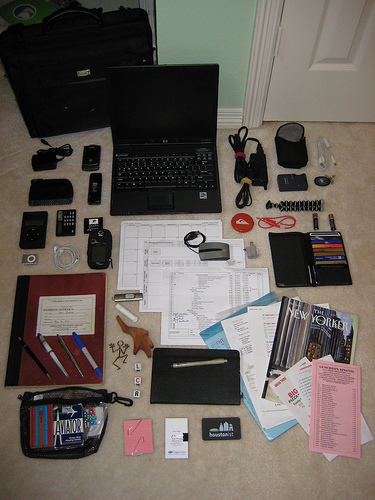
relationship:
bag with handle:
[0, 5, 161, 141] [35, 4, 107, 29]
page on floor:
[306, 356, 368, 462] [6, 119, 374, 499]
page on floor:
[290, 366, 312, 399] [6, 119, 374, 499]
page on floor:
[268, 378, 302, 426] [6, 119, 374, 499]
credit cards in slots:
[304, 225, 352, 272] [304, 225, 358, 288]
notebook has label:
[3, 265, 112, 390] [31, 290, 105, 340]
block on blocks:
[112, 214, 229, 242] [112, 220, 233, 235]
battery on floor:
[78, 172, 112, 213] [6, 119, 374, 499]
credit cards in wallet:
[304, 225, 352, 272] [264, 225, 360, 297]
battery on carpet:
[78, 139, 106, 175] [6, 119, 374, 499]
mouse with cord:
[181, 225, 237, 266] [180, 228, 209, 250]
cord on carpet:
[224, 122, 260, 214] [6, 119, 374, 499]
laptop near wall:
[97, 53, 233, 220] [158, 4, 257, 65]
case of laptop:
[143, 341, 253, 410] [97, 53, 233, 220]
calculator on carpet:
[52, 200, 82, 243] [6, 119, 374, 499]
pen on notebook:
[71, 329, 94, 357] [3, 265, 112, 390]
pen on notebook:
[59, 331, 73, 357] [3, 265, 112, 390]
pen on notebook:
[35, 330, 53, 353] [3, 265, 112, 390]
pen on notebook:
[10, 330, 33, 359] [3, 265, 112, 390]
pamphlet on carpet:
[271, 291, 372, 364] [6, 119, 374, 499]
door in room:
[260, 4, 374, 129] [9, 1, 374, 497]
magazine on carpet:
[271, 291, 372, 364] [6, 119, 374, 499]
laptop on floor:
[97, 53, 233, 220] [6, 119, 374, 499]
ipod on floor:
[83, 224, 115, 274] [6, 119, 374, 499]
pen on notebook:
[71, 329, 104, 381] [3, 265, 112, 390]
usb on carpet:
[323, 209, 345, 234] [6, 119, 374, 499]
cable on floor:
[35, 132, 80, 162] [6, 119, 374, 499]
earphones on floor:
[306, 132, 347, 194] [6, 119, 374, 499]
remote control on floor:
[83, 166, 106, 209] [6, 119, 374, 499]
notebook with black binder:
[3, 265, 112, 390] [3, 267, 29, 396]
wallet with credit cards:
[264, 225, 360, 297] [304, 225, 352, 272]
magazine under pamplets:
[271, 291, 372, 364] [206, 302, 297, 441]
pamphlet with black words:
[306, 356, 368, 462] [313, 363, 358, 451]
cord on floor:
[224, 122, 260, 214] [6, 119, 374, 499]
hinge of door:
[267, 23, 288, 60] [260, 4, 374, 129]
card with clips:
[115, 414, 158, 465] [127, 417, 145, 460]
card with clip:
[160, 413, 193, 463] [171, 429, 192, 443]